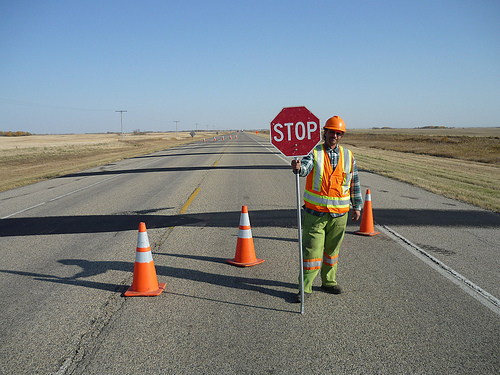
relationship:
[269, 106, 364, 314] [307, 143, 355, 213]
man wearing vest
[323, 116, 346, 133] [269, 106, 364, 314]
hard hat on man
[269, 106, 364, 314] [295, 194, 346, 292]
man wearing pants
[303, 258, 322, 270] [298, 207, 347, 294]
orange stripes on green pants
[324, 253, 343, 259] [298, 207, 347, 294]
stripe on green pants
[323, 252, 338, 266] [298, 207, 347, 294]
stripe on green pants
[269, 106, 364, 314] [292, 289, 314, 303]
man wearing sneaker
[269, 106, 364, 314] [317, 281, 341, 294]
man wearing sneaker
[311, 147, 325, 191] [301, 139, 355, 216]
patch on vest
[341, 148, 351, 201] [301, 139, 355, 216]
patch on vest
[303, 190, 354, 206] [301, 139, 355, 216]
patch on vest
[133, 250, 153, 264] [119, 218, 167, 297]
stripe on cone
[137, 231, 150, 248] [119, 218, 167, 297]
stripe on cone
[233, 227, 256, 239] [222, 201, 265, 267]
stripe on cone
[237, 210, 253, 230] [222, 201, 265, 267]
stripe on cone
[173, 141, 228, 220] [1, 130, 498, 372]
line on road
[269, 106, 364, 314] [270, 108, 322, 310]
man holding sign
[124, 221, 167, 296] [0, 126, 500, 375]
cone on ground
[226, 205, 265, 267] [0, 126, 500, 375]
cone on ground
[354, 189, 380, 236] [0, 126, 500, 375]
cone on ground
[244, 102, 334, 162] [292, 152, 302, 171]
sign in hand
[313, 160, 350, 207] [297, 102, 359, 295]
vest on man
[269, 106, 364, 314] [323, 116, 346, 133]
man wearing hard hat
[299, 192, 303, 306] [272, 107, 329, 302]
pole of the sign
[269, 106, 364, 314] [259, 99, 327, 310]
man holding sign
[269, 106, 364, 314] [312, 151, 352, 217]
man wearing vest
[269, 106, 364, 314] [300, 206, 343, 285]
man wearing pants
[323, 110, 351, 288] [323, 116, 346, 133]
man wearing hard hat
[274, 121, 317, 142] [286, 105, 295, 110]
letter on background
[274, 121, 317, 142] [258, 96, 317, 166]
letter on sign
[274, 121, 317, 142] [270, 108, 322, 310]
letter on sign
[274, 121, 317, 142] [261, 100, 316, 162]
letter on sign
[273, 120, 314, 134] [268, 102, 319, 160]
letter on sign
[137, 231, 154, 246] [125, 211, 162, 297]
stripe on cone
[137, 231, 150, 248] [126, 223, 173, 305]
stripe on cone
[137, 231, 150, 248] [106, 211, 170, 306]
stripe on cone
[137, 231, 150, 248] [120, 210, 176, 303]
stripe on cone